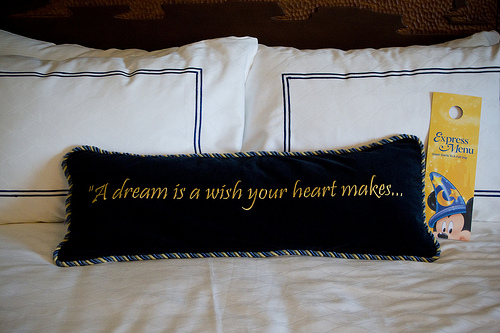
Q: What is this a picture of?
A: A bed.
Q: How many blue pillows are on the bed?
A: One.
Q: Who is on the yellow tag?
A: Mickey Mouse.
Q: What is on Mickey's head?
A: A hat.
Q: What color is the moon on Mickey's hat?
A: Yellow.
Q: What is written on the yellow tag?
A: Express Menu.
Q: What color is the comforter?
A: White.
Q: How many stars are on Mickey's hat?
A: Two.